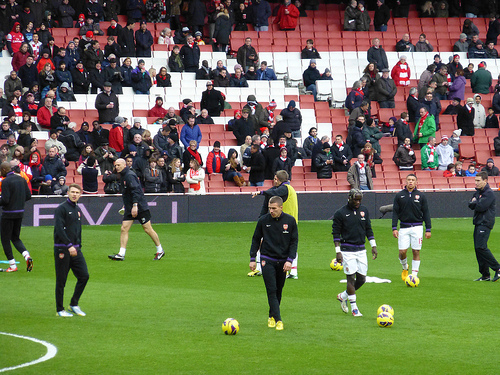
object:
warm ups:
[250, 211, 299, 323]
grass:
[30, 220, 335, 338]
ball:
[377, 304, 394, 315]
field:
[0, 217, 499, 375]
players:
[54, 184, 90, 317]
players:
[0, 160, 34, 273]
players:
[332, 188, 378, 317]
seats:
[0, 0, 499, 193]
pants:
[260, 256, 287, 323]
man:
[249, 196, 298, 330]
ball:
[221, 317, 239, 334]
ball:
[377, 312, 394, 327]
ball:
[404, 274, 419, 287]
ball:
[330, 258, 344, 271]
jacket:
[119, 166, 149, 215]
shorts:
[123, 209, 152, 225]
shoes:
[267, 317, 283, 330]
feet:
[260, 258, 287, 330]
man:
[392, 174, 431, 281]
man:
[412, 107, 436, 149]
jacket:
[414, 113, 437, 143]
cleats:
[26, 257, 33, 272]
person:
[205, 141, 228, 176]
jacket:
[205, 148, 226, 173]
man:
[108, 158, 165, 261]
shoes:
[108, 251, 166, 260]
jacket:
[392, 185, 432, 232]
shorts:
[398, 226, 423, 250]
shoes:
[401, 264, 409, 281]